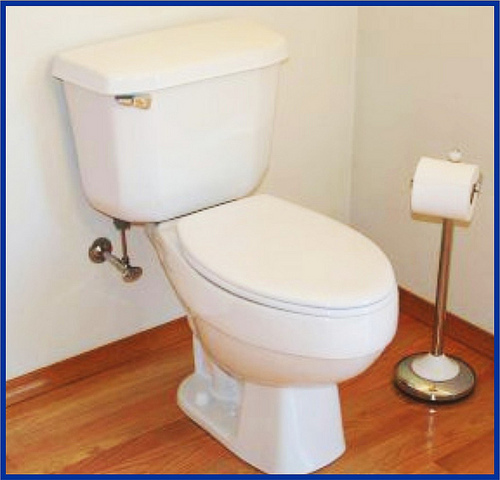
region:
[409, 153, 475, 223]
toilet paper on roll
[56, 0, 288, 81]
tank of the toilet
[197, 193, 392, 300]
lid of the toilet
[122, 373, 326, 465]
bottom of the toilet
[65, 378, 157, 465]
the floor is wood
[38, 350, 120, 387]
baseboard on the floor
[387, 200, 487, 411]
stand for toilet paper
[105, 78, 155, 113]
flusher of toilet button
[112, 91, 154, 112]
a gold toilet handle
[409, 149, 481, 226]
a roll of toilet paper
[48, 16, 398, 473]
a white toilet on a wooden floor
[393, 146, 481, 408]
a metal paper holder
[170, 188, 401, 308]
the lid of a toilet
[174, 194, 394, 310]
the cover of a toilet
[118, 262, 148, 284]
a water pressure knob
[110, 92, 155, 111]
a handle for a toilet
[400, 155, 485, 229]
a roll of paper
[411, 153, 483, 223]
a roll of bathroom paper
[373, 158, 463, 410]
toilet paper on the roll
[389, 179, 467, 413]
toilet paper on the roll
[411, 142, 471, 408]
toilet paper on the roll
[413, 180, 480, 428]
toilet paper on the roll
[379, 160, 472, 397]
toilet paper on the roll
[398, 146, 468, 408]
toilet paper on the roll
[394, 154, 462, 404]
toilet paper on the roll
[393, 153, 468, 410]
toilet paper on the roll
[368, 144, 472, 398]
toilet paper on the roll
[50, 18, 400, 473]
a white toilet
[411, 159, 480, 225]
a white roll of toilet paper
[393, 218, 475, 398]
a metal stand on the floor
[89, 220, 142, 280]
silver pipes on a toilet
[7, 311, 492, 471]
hardwood floor in a bathroom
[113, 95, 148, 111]
a silver flush handle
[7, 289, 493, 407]
wooden baseboards on the wall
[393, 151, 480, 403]
a roll of toilet paper on a stand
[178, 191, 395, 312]
a white toilet seat cover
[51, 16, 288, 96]
a white toilet lid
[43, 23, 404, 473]
A white toilet.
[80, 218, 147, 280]
Silver pipe connecting toilet to wall.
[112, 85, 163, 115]
Handle to flush toilet.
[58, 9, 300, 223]
Tank of the toilet.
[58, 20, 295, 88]
Lid on the tank.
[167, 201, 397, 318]
Lid of toilet is down.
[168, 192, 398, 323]
Ring of toilet is down.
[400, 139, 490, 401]
A toilet paper holder.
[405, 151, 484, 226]
Roll of toilet paper on holder.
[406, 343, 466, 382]
Round white section on base of toilet paper holder.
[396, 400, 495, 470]
shiny wood flooring board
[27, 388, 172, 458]
shiny wood flooring board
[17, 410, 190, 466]
shiny wood flooring board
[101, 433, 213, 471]
shiny wood flooring board